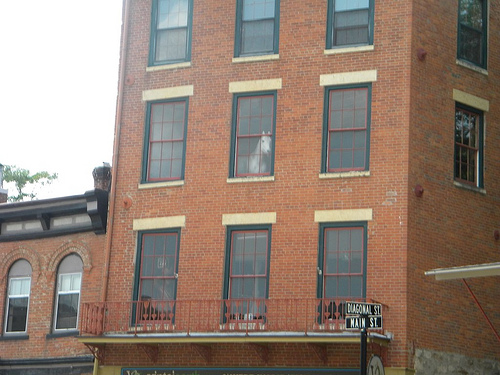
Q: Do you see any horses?
A: Yes, there is a horse.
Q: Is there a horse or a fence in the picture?
A: Yes, there is a horse.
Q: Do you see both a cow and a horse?
A: No, there is a horse but no cows.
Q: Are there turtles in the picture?
A: No, there are no turtles.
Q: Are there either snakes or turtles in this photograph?
A: No, there are no turtles or snakes.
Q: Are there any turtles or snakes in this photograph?
A: No, there are no turtles or snakes.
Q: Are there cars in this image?
A: No, there are no cars.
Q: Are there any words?
A: Yes, there are words.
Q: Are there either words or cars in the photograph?
A: Yes, there are words.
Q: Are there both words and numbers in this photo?
A: No, there are words but no numbers.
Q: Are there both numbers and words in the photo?
A: No, there are words but no numbers.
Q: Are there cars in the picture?
A: No, there are no cars.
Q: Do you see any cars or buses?
A: No, there are no cars or buses.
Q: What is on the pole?
A: The words are on the pole.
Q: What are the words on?
A: The words are on the pole.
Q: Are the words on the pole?
A: Yes, the words are on the pole.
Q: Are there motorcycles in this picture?
A: No, there are no motorcycles.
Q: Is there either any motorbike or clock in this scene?
A: No, there are no motorcycles or clocks.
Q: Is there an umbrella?
A: No, there are no umbrellas.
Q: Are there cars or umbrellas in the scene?
A: No, there are no umbrellas or cars.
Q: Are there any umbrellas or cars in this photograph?
A: No, there are no umbrellas or cars.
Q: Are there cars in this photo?
A: No, there are no cars.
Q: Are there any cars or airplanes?
A: No, there are no cars or airplanes.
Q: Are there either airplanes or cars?
A: No, there are no cars or airplanes.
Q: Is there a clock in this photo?
A: No, there are no clocks.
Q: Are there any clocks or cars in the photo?
A: No, there are no clocks or cars.